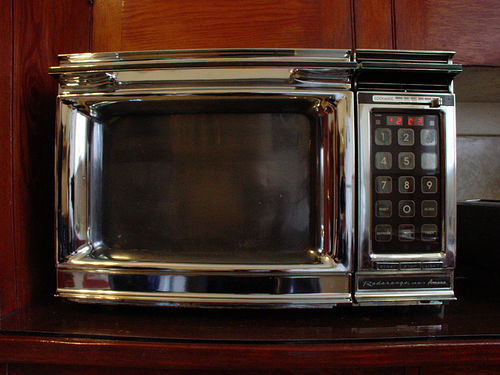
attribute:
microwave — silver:
[46, 43, 466, 325]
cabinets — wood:
[89, 0, 493, 45]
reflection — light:
[62, 107, 108, 174]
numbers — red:
[392, 111, 427, 130]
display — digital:
[369, 109, 443, 130]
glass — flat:
[7, 272, 494, 336]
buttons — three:
[371, 260, 450, 279]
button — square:
[414, 193, 442, 222]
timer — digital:
[382, 114, 427, 126]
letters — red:
[385, 114, 424, 125]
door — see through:
[102, 105, 322, 264]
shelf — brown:
[0, 342, 488, 373]